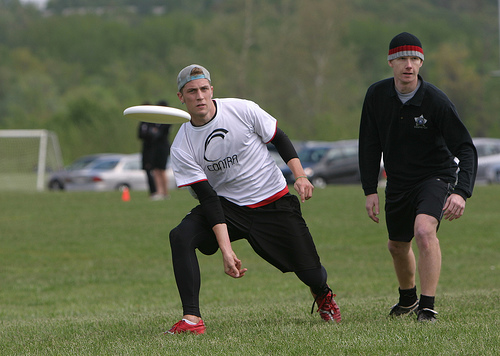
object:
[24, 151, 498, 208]
these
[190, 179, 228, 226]
sleeve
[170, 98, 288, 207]
shirt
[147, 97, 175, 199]
people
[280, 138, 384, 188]
vehicles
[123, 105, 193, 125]
disk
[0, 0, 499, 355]
air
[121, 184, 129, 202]
cone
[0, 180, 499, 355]
field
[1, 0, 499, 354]
park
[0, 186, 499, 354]
ground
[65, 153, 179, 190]
cars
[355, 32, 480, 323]
man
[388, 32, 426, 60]
cap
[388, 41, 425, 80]
head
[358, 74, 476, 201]
shirt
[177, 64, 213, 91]
hat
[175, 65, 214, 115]
head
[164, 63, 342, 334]
man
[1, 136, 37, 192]
net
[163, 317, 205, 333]
shoe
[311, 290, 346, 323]
shoe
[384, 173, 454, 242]
pants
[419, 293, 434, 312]
sock